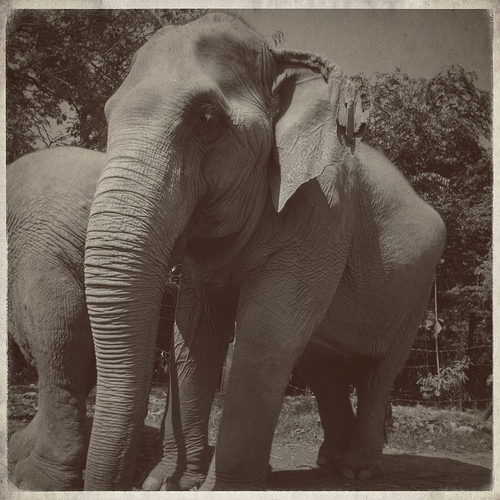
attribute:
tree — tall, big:
[7, 7, 203, 147]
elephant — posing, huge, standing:
[77, 12, 452, 494]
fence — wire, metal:
[159, 274, 496, 407]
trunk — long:
[79, 129, 207, 495]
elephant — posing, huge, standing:
[3, 145, 105, 489]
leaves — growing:
[419, 357, 473, 407]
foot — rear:
[315, 435, 347, 472]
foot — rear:
[337, 440, 386, 483]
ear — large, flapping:
[274, 46, 374, 212]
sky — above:
[233, 8, 493, 82]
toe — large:
[341, 465, 355, 483]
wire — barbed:
[411, 343, 495, 355]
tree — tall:
[350, 60, 489, 346]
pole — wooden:
[431, 271, 444, 375]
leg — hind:
[295, 354, 355, 470]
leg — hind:
[340, 372, 395, 484]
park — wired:
[1, 255, 491, 490]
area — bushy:
[7, 264, 491, 409]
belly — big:
[329, 140, 457, 357]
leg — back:
[12, 258, 85, 490]